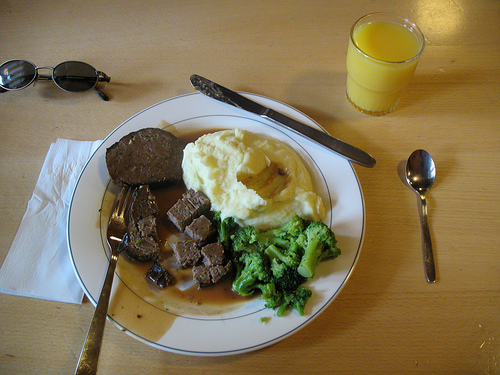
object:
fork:
[73, 182, 140, 375]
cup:
[344, 12, 425, 116]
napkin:
[0, 138, 103, 305]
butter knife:
[188, 72, 378, 168]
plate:
[64, 90, 365, 359]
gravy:
[95, 120, 248, 344]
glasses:
[0, 59, 111, 102]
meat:
[103, 125, 233, 289]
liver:
[166, 188, 208, 230]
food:
[101, 126, 346, 318]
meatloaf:
[104, 127, 186, 187]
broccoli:
[212, 212, 342, 318]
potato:
[180, 128, 327, 228]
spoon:
[405, 148, 437, 283]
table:
[0, 0, 500, 375]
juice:
[344, 21, 420, 110]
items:
[0, 11, 437, 375]